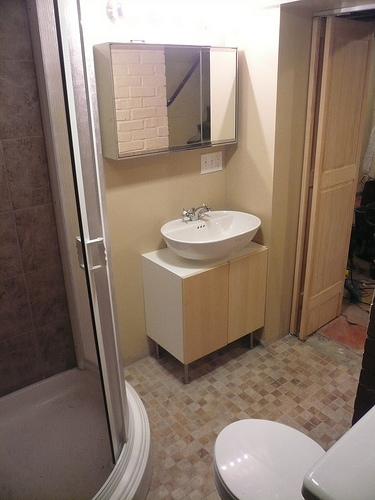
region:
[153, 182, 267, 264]
the sink is white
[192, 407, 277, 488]
the toilet seat is closed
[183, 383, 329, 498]
the toilet seat is closed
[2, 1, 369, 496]
A bright bathroom.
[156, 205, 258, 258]
The bathroom sink is oval shaped.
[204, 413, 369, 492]
The toilet is in white porcelain.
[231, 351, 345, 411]
The bathroom floor tiles have a mixture of beige, brown and tan colors.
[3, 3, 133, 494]
Shower with sliding glass door.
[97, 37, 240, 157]
Large rectangular mirror above the sink.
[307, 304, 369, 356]
The doorstep entrance is damaged.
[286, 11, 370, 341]
Wooden folding door.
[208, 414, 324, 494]
The toilet cover sit is down.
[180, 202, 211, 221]
Faucet is silver.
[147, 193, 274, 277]
There is a white sink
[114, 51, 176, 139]
White painted brick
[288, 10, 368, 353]
A wooden folding door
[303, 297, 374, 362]
An orange rug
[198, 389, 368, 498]
A white toilet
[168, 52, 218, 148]
A staircase in the mirror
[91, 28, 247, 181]
A medicine cabinet on the wall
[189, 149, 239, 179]
Multiple light switch on the wall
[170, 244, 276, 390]
A double door cabinet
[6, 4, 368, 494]
A neat and clean bathroom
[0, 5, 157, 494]
Enclosed shower area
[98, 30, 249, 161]
Cabinet with mirrors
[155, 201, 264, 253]
White wash basin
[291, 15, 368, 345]
Beige bathroom door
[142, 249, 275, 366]
Beige and white vanity cabinet underneath washbasin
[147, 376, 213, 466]
Light and brown tiles on the floor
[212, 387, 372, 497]
White commode and tank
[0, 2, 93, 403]
Grey wall in the shower area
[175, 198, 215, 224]
Chromed silver faucet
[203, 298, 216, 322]
DOORS MADE OUT OF WOOD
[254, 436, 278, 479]
TOILET TOP IS CLOSED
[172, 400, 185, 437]
TILE ON THE FLOOR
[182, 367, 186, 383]
LEGS ARE MADE OUT OF IRON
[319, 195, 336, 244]
DOOR MADE OUT OF WOOD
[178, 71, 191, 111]
GLASS MIRROR ON THE WALL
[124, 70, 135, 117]
WALL MADE OUT OF BRICK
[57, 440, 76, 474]
SHOWER FLOOR ARE CLEAN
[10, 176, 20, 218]
TILE ON THE WALL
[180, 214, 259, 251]
WHITE SINK BOWL ON TOP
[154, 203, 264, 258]
Large white ceramic sink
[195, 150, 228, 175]
Wall mounted white power outlets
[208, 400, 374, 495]
White, ceramic, bathroom toilet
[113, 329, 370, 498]
Cream and beige tiled floor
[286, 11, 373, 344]
Tall light brown wooden door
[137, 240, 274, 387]
White cabinet with light wood coloring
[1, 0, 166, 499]
Large bathroom shower stall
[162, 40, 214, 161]
Clean bathroom mirror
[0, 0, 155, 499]
dark brown tiles in shower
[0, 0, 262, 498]
shower next to sink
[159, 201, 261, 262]
white bowl sink has silver faucet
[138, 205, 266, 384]
white cabinet under sink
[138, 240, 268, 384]
white cabinet has wooden doors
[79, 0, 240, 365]
mirror on wall above sink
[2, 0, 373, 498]
white toilet in front of shower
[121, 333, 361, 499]
beige and brown tiled floor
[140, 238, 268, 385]
cabinet has silver legs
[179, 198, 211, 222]
sink handle is made of silver